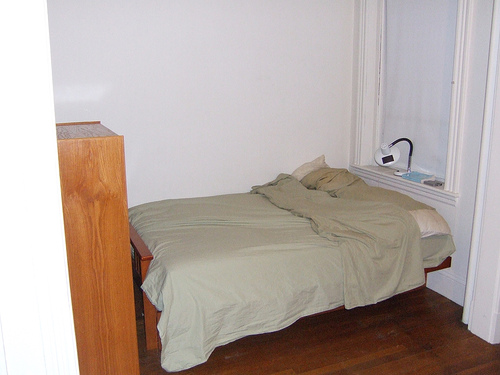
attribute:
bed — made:
[129, 154, 455, 372]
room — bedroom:
[0, 1, 499, 374]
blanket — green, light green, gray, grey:
[127, 173, 425, 371]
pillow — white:
[410, 207, 452, 238]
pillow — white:
[292, 155, 330, 180]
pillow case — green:
[337, 183, 436, 210]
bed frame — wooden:
[128, 222, 451, 350]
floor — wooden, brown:
[134, 277, 499, 374]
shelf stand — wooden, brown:
[55, 121, 141, 374]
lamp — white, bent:
[374, 137, 413, 176]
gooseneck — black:
[389, 137, 414, 172]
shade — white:
[378, 0, 458, 181]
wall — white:
[47, 0, 355, 210]